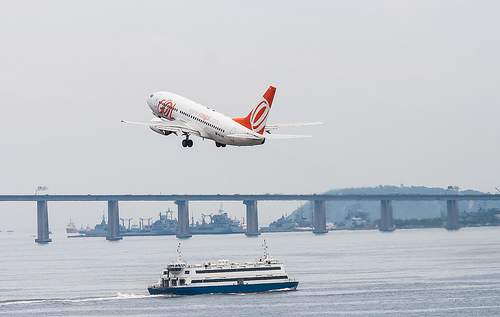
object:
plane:
[118, 84, 323, 150]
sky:
[0, 8, 500, 229]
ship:
[146, 238, 300, 297]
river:
[0, 214, 499, 316]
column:
[35, 199, 51, 243]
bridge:
[0, 188, 500, 243]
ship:
[60, 214, 85, 239]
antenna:
[254, 235, 272, 265]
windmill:
[134, 214, 145, 233]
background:
[0, 0, 499, 315]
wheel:
[180, 139, 194, 147]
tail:
[233, 84, 279, 142]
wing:
[118, 116, 200, 135]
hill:
[257, 184, 494, 234]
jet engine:
[144, 115, 176, 138]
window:
[174, 106, 182, 115]